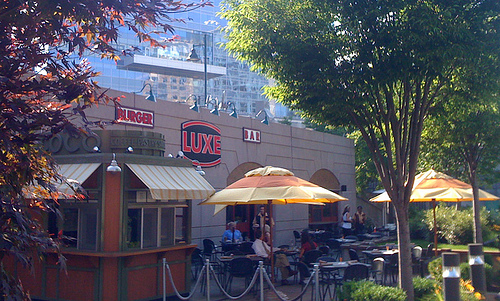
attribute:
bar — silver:
[156, 253, 174, 299]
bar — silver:
[199, 253, 219, 299]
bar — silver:
[255, 254, 272, 298]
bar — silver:
[309, 257, 327, 298]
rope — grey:
[163, 258, 207, 298]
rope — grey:
[208, 260, 260, 299]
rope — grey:
[262, 267, 314, 296]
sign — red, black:
[176, 118, 237, 176]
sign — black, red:
[173, 120, 229, 170]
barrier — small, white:
[467, 240, 488, 300]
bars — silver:
[157, 248, 174, 299]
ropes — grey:
[161, 256, 211, 299]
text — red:
[178, 111, 241, 165]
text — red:
[114, 100, 163, 125]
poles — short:
[432, 237, 494, 295]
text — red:
[114, 107, 156, 129]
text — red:
[182, 129, 222, 154]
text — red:
[244, 124, 259, 144]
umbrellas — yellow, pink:
[194, 162, 499, 210]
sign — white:
[113, 105, 155, 127]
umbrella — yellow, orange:
[358, 163, 499, 217]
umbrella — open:
[209, 128, 339, 225]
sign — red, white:
[111, 100, 156, 137]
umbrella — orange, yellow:
[208, 162, 348, 212]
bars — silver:
[256, 260, 267, 300]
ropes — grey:
[259, 260, 311, 300]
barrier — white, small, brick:
[449, 248, 496, 283]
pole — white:
[308, 259, 323, 299]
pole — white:
[253, 257, 268, 299]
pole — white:
[201, 255, 213, 298]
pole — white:
[157, 254, 170, 298]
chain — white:
[163, 264, 315, 297]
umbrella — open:
[203, 165, 347, 202]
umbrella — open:
[371, 166, 499, 201]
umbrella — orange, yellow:
[197, 162, 349, 292]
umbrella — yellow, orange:
[189, 159, 352, 229]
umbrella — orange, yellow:
[369, 164, 498, 254]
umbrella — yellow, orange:
[367, 167, 497, 269]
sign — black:
[181, 117, 223, 171]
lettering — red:
[115, 107, 153, 126]